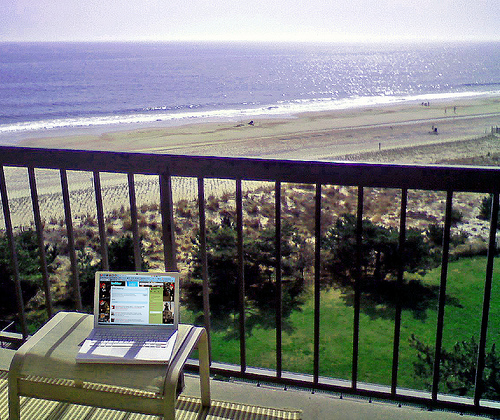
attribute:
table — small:
[9, 312, 210, 418]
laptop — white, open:
[75, 272, 180, 363]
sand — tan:
[5, 92, 496, 228]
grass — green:
[179, 251, 491, 391]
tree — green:
[327, 214, 373, 290]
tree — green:
[387, 227, 442, 292]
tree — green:
[202, 221, 245, 322]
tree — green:
[0, 232, 36, 318]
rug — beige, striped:
[1, 367, 302, 416]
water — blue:
[3, 38, 499, 134]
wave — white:
[7, 110, 154, 123]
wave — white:
[261, 94, 398, 120]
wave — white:
[408, 84, 488, 102]